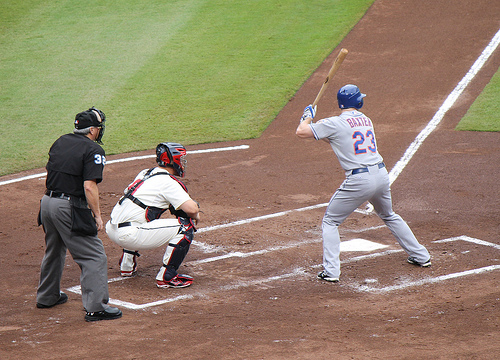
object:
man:
[34, 106, 121, 322]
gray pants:
[36, 195, 109, 312]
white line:
[0, 145, 249, 186]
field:
[0, 0, 500, 360]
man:
[294, 47, 433, 282]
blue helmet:
[337, 84, 366, 110]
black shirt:
[45, 132, 105, 198]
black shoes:
[35, 293, 121, 323]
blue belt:
[352, 163, 385, 175]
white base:
[339, 238, 389, 252]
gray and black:
[61, 171, 68, 216]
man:
[104, 142, 200, 288]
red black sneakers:
[119, 267, 194, 289]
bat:
[313, 47, 348, 107]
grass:
[0, 1, 500, 182]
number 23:
[352, 130, 376, 155]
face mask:
[91, 105, 105, 145]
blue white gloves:
[299, 104, 317, 122]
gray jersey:
[306, 109, 383, 169]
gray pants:
[319, 168, 430, 278]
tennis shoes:
[317, 257, 431, 283]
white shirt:
[110, 167, 191, 226]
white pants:
[103, 218, 183, 280]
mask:
[156, 141, 187, 178]